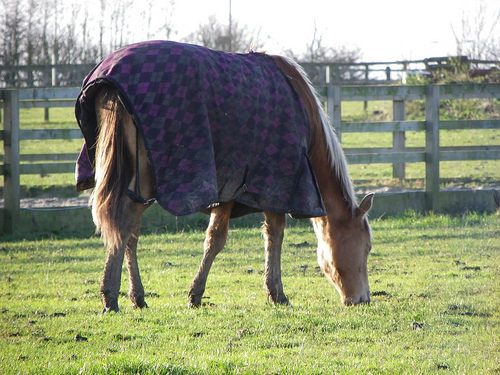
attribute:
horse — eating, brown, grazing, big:
[64, 36, 382, 311]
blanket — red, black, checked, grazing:
[100, 44, 314, 219]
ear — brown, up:
[360, 190, 384, 233]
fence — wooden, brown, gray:
[425, 79, 499, 185]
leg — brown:
[204, 209, 235, 295]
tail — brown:
[87, 111, 138, 232]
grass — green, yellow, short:
[242, 310, 288, 332]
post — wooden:
[424, 70, 448, 195]